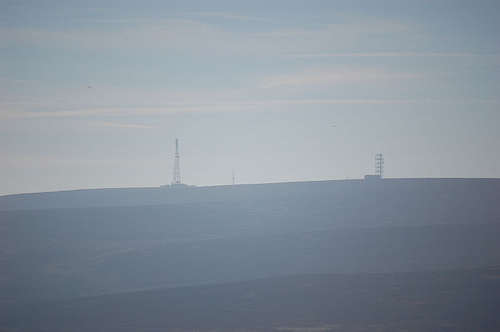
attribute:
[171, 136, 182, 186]
tower — tall, cell phone tower, alone, cell tower, distant, telephone tower, metal, large, in shadow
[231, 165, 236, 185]
structure — small, distant, gray, short, electric power tower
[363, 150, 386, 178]
structure — power pole, a grid tower, distant, electric pole tower, for electricity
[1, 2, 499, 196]
sky — cloudy, blue, light blue, patterned, foggy, clouded, clear, gray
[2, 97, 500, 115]
cloud — long, thin, pink, wispy, line, yellow, orange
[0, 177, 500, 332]
ground — dark, hilly, dimly lit, hazy, dry, foggy, ascending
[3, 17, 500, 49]
cloud — white, fluffy, pink, orange, long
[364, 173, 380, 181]
building — small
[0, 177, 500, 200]
horizon — clear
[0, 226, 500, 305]
hill — four